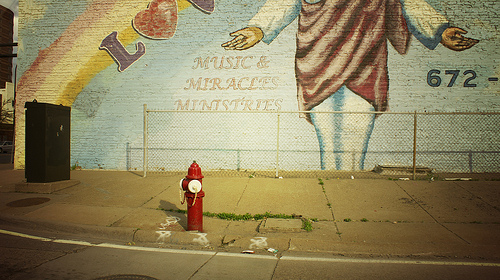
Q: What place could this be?
A: It is a pavement.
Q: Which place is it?
A: It is a pavement.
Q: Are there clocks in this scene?
A: No, there are no clocks.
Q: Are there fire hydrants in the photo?
A: Yes, there is a fire hydrant.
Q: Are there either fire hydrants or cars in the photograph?
A: Yes, there is a fire hydrant.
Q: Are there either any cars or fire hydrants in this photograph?
A: Yes, there is a fire hydrant.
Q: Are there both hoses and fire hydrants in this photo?
A: No, there is a fire hydrant but no hoses.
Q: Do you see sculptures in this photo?
A: No, there are no sculptures.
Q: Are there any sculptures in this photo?
A: No, there are no sculptures.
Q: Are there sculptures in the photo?
A: No, there are no sculptures.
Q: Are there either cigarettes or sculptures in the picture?
A: No, there are no sculptures or cigarettes.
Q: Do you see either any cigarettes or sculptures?
A: No, there are no sculptures or cigarettes.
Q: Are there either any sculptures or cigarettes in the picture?
A: No, there are no sculptures or cigarettes.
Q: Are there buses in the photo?
A: No, there are no buses.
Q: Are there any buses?
A: No, there are no buses.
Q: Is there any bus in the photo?
A: No, there are no buses.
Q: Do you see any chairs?
A: No, there are no chairs.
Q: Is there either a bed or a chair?
A: No, there are no chairs or beds.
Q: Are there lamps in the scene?
A: No, there are no lamps.